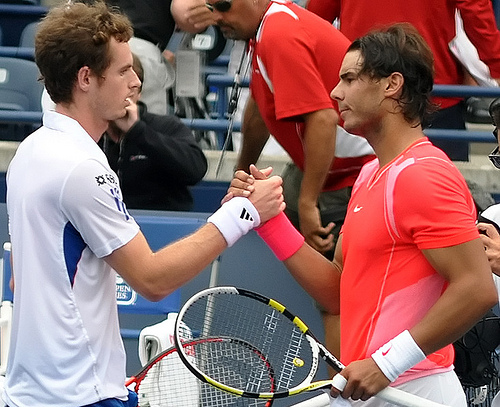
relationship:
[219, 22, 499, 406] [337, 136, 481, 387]
man wearing a shirt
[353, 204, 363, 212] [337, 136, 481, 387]
nike logo on shirt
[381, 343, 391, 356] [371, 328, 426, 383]
nike logo on wrist band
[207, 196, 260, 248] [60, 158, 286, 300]
wrist band on arm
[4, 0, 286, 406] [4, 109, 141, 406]
man wearing a shirt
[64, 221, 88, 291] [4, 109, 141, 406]
patch on shirt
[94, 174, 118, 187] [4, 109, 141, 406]
lettering on shirt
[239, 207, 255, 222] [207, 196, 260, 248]
logo on wrist band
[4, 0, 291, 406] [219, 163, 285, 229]
man shaking hands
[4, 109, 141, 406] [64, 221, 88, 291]
shirt has a blue patch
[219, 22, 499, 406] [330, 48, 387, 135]
man has a game face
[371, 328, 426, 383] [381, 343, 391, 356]
wrist band has a pink nike logo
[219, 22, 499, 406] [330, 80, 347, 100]
man has a nose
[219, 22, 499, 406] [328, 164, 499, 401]
man has an arm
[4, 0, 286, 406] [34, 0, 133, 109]
man has hair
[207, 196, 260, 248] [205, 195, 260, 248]
wrist band on mans wrist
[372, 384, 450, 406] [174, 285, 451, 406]
grip on tennis racket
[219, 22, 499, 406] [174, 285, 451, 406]
man holding tennis racket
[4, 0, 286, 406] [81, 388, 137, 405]
man wearing shorts